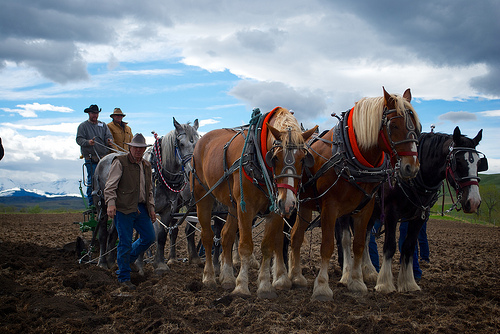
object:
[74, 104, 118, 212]
man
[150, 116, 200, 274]
horse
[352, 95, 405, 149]
mane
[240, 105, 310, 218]
bridle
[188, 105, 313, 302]
horse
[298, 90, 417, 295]
horse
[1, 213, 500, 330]
dirt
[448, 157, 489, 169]
blinder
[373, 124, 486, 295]
horse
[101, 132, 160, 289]
man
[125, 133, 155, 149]
cowboy hat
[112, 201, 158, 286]
jeans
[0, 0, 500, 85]
cloud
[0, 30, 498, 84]
sky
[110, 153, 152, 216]
vest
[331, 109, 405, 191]
bridle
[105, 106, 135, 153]
man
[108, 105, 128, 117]
cowboy hat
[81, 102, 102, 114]
cowboy hat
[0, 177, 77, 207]
mountains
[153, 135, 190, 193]
bridle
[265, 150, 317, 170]
blinder